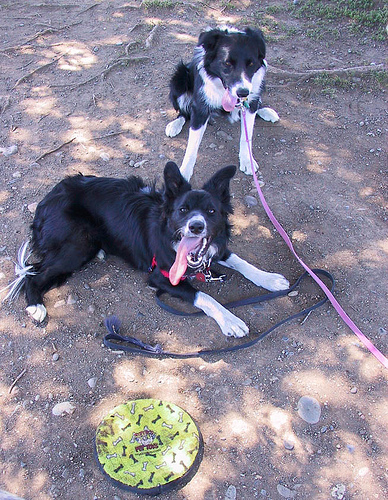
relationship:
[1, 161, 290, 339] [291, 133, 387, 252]
dog on ground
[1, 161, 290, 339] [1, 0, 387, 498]
dog on ground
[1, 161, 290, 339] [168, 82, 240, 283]
dog have toungues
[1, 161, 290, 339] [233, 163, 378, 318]
dog have leash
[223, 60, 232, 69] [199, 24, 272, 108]
brown eye on head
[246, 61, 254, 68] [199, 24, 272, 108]
brown eye on head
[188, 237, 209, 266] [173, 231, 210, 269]
teeth in mouth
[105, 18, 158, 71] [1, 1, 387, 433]
tree roots in dirt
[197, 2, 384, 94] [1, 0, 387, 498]
grass on ground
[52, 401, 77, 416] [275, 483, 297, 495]
rock on ground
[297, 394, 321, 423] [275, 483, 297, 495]
rock on ground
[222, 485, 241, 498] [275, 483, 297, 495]
rock on ground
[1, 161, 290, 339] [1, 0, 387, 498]
dog sitting in dirt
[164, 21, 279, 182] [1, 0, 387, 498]
dog sitting in dirt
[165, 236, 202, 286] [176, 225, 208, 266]
tongue hanging out of mouth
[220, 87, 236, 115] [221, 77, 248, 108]
tongue hanging out of mouth